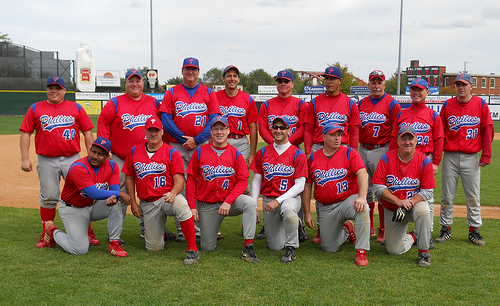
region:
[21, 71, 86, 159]
player wearing red white and blue uniform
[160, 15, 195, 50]
white clouds in blue sky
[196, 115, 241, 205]
player wearing red white and blue uniform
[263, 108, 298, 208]
player wearing red white and blue uniform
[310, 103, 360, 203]
player wearing red white and blue uniform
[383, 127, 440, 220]
player wearing red white and blue uniform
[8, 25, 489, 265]
A team posing for a picture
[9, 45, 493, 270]
A baseball team posing for the camera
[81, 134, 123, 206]
The man is looking away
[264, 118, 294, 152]
The man has glasses on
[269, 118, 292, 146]
The man has sunglasses on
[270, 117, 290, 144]
The man is smiling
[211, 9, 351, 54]
Clouds in the sky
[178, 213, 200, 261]
The man has a sock on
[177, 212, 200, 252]
The man has a red sock on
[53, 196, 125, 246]
The man is wearing pants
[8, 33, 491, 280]
Team posing for a picture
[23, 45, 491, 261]
Baseball team posing for a picture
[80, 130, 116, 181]
The man is looking away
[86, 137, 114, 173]
The man is wearing a hat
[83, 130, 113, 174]
The man is wearing a cap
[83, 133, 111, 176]
The man is wearing a baseball cap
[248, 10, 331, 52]
White clouds in the sky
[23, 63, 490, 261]
Baseball players posing for a photo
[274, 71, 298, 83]
Blue and red cap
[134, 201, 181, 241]
Gray pants in the photo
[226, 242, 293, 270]
Black shoes in the photo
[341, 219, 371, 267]
Red shoes in the photo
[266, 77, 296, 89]
Eyeglasses in the photo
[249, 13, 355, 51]
Clouds in the background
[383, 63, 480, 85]
Buildings in the background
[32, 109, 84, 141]
Writings on the jersey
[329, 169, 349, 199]
Number on the jersey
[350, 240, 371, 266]
one red baseball cleat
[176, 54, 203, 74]
blue and red baseball cap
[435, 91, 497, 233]
red, blue and grey baseball uniform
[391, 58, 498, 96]
brick building behind baseball players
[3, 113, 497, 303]
grass covered baseball field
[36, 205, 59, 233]
knee length red sock on baseball player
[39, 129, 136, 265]
baseball player kneeling with one knee on ground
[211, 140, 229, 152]
red collar of grey shirt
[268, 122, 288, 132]
pair of sunglasses on baseball player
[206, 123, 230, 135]
pair of eye glasses on baseball player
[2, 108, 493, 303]
a baseball field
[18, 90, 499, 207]
all the jerseys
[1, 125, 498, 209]
the red dirt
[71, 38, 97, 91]
the white carton